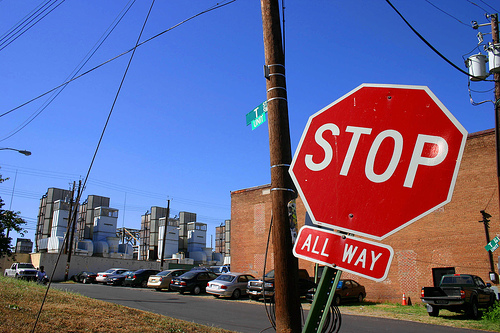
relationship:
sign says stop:
[290, 84, 470, 240] [304, 123, 449, 188]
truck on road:
[4, 260, 36, 280] [46, 280, 488, 332]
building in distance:
[229, 126, 498, 306] [0, 1, 499, 218]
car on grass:
[206, 272, 260, 298] [1, 281, 240, 331]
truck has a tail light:
[4, 260, 36, 280] [422, 287, 426, 298]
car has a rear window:
[206, 272, 260, 298] [216, 272, 236, 283]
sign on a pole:
[290, 84, 470, 240] [300, 267, 343, 333]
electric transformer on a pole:
[467, 54, 487, 79] [490, 13, 498, 196]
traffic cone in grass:
[402, 294, 408, 306] [1, 281, 240, 331]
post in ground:
[262, 1, 302, 333] [3, 277, 499, 331]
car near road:
[206, 272, 260, 298] [46, 280, 488, 332]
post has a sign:
[262, 1, 302, 333] [290, 84, 470, 240]